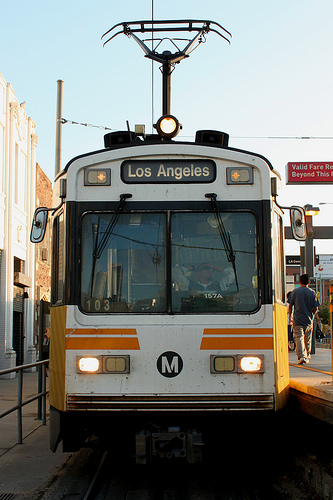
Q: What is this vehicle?
A: Commuter train.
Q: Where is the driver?
A: Seated in the front.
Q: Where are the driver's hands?
A: On top of his head.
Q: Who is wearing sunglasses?
A: Driver.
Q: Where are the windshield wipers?
A: On the windshield.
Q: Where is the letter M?
A: On the front of the train.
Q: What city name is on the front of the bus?
A: Los angeles.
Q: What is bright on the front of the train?
A: Headlights.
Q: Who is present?
A: People.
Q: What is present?
A: A train.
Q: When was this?
A: Daytime.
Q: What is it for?
A: Transport.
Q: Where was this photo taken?
A: At a track stop.